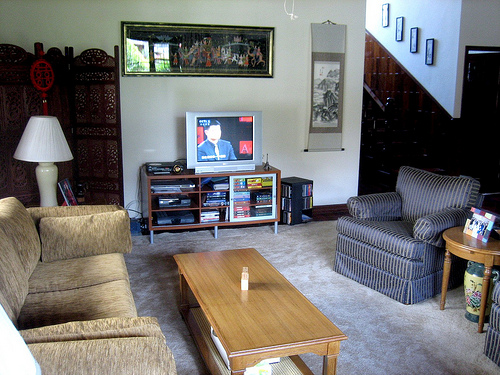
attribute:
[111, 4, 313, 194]
wall — white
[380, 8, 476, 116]
wall — white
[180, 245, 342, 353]
table — wood, brown, rectangular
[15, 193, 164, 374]
sofa — tan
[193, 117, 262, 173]
tv — grey, square, silver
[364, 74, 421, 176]
stairs — wooden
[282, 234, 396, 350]
floor — tan, light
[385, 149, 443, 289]
chair — striped, blue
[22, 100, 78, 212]
lamp — white, tan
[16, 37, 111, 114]
room divider — brown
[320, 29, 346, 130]
scroll — tan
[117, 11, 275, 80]
art — black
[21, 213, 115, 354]
couch — brown, long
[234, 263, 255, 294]
bottle — white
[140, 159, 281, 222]
stand — wood, brown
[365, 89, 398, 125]
railing — wood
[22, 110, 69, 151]
lampshade — white, fabric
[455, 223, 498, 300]
table — brown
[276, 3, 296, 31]
rope — white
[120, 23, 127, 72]
frame — black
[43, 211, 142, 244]
cushion — brown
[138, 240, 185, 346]
carpet — tan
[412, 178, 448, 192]
stripes — white